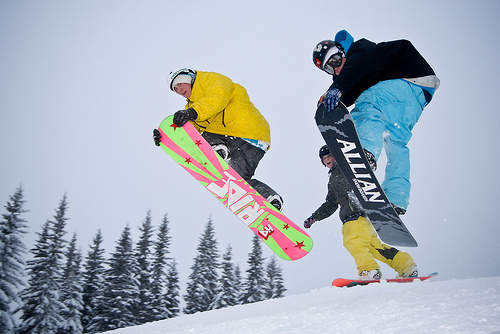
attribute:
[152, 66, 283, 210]
person — white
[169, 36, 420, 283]
people — snowboarding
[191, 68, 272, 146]
jacket — yellow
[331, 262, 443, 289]
snowboard — orange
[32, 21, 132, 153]
clouds — white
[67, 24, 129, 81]
sky — blue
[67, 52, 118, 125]
clouds — white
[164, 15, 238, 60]
sky — blue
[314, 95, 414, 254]
snowboard — white, blue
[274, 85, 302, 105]
clouds — white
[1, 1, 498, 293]
sky — blue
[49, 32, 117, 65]
clouds — white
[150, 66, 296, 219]
snowboarder — aired